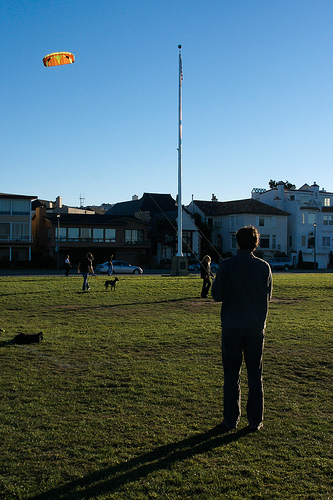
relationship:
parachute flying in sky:
[39, 39, 81, 78] [6, 9, 324, 174]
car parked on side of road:
[96, 254, 144, 274] [27, 248, 145, 278]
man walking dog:
[72, 252, 93, 296] [100, 273, 121, 294]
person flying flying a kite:
[212, 225, 273, 427] [38, 38, 221, 300]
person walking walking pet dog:
[76, 249, 98, 293] [72, 250, 123, 297]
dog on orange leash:
[101, 275, 120, 289] [91, 270, 104, 285]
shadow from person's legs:
[31, 419, 251, 498] [216, 327, 269, 429]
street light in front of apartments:
[310, 220, 320, 276] [256, 168, 331, 276]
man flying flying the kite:
[203, 217, 282, 425] [43, 50, 216, 301]